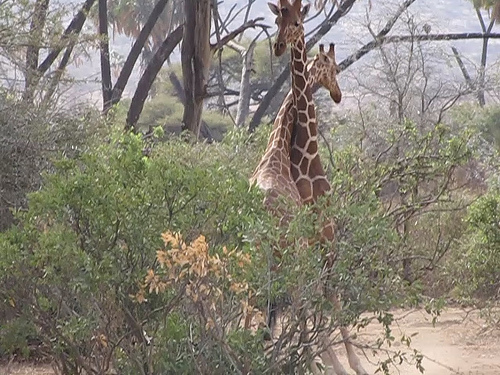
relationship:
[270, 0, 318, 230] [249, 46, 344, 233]
giraffe hugging giraffe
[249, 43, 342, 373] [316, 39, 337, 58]
giraffe has ears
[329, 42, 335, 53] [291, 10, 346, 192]
horn on giraffe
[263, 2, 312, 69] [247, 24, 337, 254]
head on giraffe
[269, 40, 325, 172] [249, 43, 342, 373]
neck on giraffe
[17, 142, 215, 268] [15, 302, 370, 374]
leaves on branches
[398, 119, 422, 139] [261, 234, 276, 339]
leaf on branch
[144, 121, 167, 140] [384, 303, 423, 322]
leaf on branch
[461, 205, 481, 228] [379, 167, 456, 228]
leaf on branch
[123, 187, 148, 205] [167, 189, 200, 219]
leaf on branch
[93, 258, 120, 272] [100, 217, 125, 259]
leaf on branch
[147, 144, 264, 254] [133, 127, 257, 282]
leaves on branches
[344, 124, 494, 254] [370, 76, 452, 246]
leaves on branches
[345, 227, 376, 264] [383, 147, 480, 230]
leaves on branches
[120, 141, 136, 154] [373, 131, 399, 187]
leaves on branches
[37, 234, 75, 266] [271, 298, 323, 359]
leaves on branches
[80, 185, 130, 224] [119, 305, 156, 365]
leaves on branches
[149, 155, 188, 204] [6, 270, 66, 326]
leaves on branches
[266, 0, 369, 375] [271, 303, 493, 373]
giraffe standing on dirt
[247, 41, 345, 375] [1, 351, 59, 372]
giraffe standing on dirt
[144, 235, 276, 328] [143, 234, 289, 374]
leaves on branches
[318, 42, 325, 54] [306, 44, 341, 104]
horn at top of head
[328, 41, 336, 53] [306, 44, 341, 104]
horn at top of head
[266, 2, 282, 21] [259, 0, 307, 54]
ear sticking out side head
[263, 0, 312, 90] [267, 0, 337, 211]
head on giraffe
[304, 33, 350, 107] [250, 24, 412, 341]
head on giraffe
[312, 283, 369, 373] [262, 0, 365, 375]
front legs on giraffe